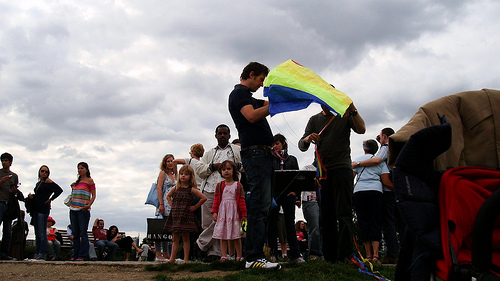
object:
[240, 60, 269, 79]
hair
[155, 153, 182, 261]
woman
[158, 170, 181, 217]
dress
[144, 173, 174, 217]
bag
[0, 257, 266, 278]
sand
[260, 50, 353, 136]
kite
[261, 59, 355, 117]
flag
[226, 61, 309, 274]
man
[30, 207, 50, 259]
jeans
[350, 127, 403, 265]
man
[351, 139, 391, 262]
woman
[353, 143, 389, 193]
shirts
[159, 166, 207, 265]
girl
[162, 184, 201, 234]
dress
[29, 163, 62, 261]
blackshirt woman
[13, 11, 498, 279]
photo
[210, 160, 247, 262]
girl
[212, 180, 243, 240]
dress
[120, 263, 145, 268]
cement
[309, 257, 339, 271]
grass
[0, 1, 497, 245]
sky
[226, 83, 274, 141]
shirt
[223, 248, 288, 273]
shoes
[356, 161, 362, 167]
watch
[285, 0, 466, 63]
clouds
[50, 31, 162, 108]
clouds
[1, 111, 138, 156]
clouds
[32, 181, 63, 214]
t-shirt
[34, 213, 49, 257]
pants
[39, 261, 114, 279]
ground